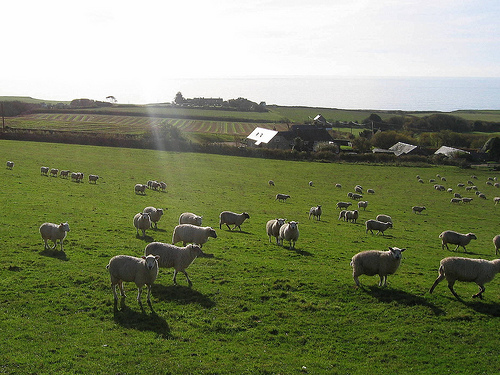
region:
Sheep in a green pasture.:
[0, 22, 497, 372]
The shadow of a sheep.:
[357, 275, 444, 326]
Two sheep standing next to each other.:
[258, 206, 303, 253]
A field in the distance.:
[20, 108, 271, 135]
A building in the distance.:
[235, 120, 296, 156]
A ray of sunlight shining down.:
[127, 80, 217, 220]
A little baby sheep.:
[20, 205, 81, 261]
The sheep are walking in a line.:
[23, 151, 108, 189]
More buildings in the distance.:
[352, 125, 488, 166]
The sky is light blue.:
[285, 73, 492, 98]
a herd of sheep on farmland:
[0, 157, 498, 373]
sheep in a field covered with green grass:
[5, 159, 499, 319]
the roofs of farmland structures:
[389, 127, 469, 158]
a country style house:
[245, 125, 336, 151]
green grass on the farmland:
[201, 289, 346, 373]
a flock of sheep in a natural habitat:
[3, 157, 498, 347]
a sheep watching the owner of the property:
[104, 252, 159, 309]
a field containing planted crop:
[20, 112, 244, 136]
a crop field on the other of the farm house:
[29, 111, 242, 135]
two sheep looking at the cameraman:
[265, 216, 301, 251]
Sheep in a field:
[36, 155, 499, 331]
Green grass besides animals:
[232, 277, 391, 373]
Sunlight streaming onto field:
[141, 105, 199, 207]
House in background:
[384, 133, 421, 161]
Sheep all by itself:
[36, 212, 71, 251]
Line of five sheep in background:
[34, 155, 101, 190]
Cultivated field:
[32, 109, 246, 136]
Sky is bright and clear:
[13, 13, 489, 105]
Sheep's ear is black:
[388, 242, 391, 254]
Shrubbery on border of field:
[16, 125, 497, 168]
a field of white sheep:
[5, 156, 498, 311]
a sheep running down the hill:
[216, 208, 251, 235]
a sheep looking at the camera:
[103, 254, 164, 307]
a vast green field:
[0, 91, 498, 373]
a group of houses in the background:
[240, 111, 475, 156]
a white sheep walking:
[142, 237, 204, 288]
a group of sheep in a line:
[36, 164, 99, 184]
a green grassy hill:
[0, 136, 499, 372]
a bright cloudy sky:
[4, 0, 498, 110]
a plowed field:
[0, 114, 296, 136]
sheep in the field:
[38, 147, 465, 324]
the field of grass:
[118, 150, 450, 353]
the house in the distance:
[239, 125, 302, 151]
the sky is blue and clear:
[319, 23, 472, 83]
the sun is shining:
[22, 16, 215, 83]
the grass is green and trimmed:
[249, 285, 339, 351]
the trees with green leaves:
[397, 113, 464, 134]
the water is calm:
[311, 77, 478, 106]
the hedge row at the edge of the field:
[22, 136, 302, 162]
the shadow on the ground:
[96, 304, 180, 346]